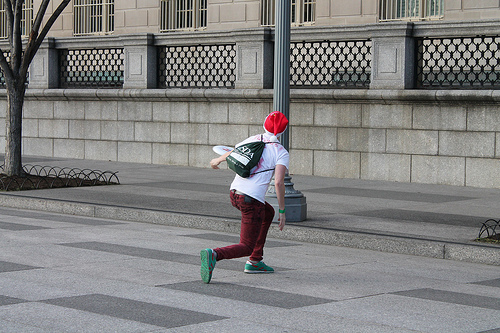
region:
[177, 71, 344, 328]
Person wearing a santa hat.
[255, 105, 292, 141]
A red and white hat.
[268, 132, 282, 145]
White fuzzy ball on end of hat.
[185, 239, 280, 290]
Pair of green tennis shoes.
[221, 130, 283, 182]
A black backpack.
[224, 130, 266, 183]
White graphics on backpack.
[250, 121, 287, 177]
Straps for the backpack.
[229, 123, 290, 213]
A white short sleeve shirt.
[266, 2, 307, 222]
A tall grey pole.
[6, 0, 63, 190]
Tree with no leaves.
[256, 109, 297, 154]
a red santa hat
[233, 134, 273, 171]
a black and white bag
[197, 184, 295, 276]
maroon pants on a man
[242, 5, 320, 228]
a large grey post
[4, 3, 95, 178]
a tree growing in a sidewalk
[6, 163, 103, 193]
brown dirt around the base of a tree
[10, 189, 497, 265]
a curb on a walkway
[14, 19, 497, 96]
concrete railing on an upper walkway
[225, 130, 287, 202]
a white shirt on a man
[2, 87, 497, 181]
a concrete wall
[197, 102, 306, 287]
person wearing red Santa hat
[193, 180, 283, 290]
person wearing dark red pants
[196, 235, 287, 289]
person wearing bright green sneakers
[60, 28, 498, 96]
black patterned fencing inside stone columns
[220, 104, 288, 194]
person wearing dark green backpack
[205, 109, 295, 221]
person wearing white t shirt with red lettering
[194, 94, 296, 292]
person throwing white frisbee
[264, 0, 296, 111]
grayish green long column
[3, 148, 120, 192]
semicircular wire fencing along bottom of tree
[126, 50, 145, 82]
rectangular detail on gray stone column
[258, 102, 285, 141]
red santa hat on person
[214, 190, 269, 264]
maroon jeans on person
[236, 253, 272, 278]
green shoes on person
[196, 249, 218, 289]
green shoe on person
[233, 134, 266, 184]
back pack on person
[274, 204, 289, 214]
green wristband on person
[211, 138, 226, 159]
frisbee in person's hand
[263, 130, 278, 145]
white pom pom on end of hat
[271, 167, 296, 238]
right arm on person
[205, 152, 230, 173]
left arm of person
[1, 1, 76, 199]
A tree is to the left.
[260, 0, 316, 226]
A lamp post.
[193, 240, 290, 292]
The person is wearing green shoes.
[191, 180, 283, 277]
The person is wearing red pants.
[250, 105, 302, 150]
The person is wearing a red hat.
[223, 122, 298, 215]
The person is wearing a white shirt.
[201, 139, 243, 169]
The person is catching a frisbee.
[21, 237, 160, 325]
The ground is made of stone blocks.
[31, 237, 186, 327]
The sidewalk is gray.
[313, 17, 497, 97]
A stone guardrail.